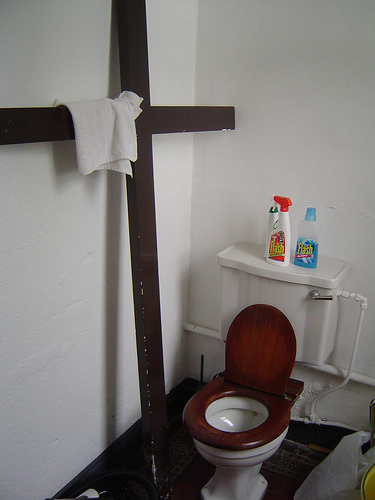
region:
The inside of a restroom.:
[4, 0, 369, 497]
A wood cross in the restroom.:
[4, 0, 233, 489]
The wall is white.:
[24, 216, 110, 421]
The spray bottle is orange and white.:
[262, 184, 292, 271]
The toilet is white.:
[177, 240, 350, 497]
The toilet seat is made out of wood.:
[180, 376, 294, 451]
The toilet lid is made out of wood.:
[215, 307, 292, 394]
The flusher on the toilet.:
[309, 286, 334, 305]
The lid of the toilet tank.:
[213, 233, 348, 286]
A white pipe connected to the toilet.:
[294, 281, 374, 436]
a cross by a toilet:
[43, 96, 329, 359]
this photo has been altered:
[86, 164, 342, 440]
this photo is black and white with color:
[121, 201, 350, 439]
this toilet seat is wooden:
[159, 303, 303, 461]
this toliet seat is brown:
[188, 315, 301, 447]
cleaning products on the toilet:
[221, 189, 343, 285]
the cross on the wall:
[8, 8, 251, 258]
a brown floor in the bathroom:
[59, 380, 310, 499]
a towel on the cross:
[38, 76, 183, 185]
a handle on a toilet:
[300, 283, 349, 318]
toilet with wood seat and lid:
[181, 234, 336, 498]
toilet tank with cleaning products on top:
[210, 176, 359, 367]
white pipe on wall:
[185, 317, 371, 392]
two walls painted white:
[6, 2, 358, 470]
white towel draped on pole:
[9, 5, 251, 478]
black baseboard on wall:
[2, 354, 372, 498]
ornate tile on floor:
[130, 401, 359, 497]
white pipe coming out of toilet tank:
[293, 268, 363, 441]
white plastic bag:
[290, 413, 373, 499]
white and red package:
[264, 193, 291, 267]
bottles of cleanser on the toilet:
[230, 178, 329, 276]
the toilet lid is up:
[191, 296, 297, 430]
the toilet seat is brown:
[167, 300, 307, 481]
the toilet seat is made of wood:
[171, 315, 291, 442]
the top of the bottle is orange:
[260, 192, 294, 216]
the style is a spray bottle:
[252, 175, 295, 222]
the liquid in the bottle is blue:
[289, 227, 326, 270]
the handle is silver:
[293, 275, 344, 318]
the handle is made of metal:
[297, 282, 334, 321]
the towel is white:
[32, 72, 182, 200]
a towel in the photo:
[61, 80, 142, 173]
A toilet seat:
[183, 377, 296, 472]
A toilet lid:
[227, 307, 292, 398]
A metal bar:
[136, 180, 172, 343]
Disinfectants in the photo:
[257, 183, 321, 270]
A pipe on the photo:
[340, 324, 364, 397]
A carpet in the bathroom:
[282, 446, 322, 471]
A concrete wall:
[32, 209, 98, 322]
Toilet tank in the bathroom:
[204, 246, 344, 368]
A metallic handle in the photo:
[308, 289, 335, 302]